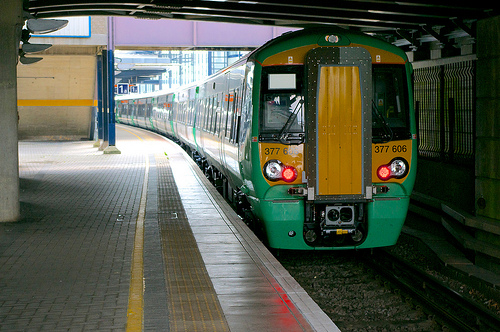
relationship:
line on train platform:
[112, 125, 160, 330] [7, 113, 279, 330]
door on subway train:
[315, 61, 367, 209] [114, 27, 427, 254]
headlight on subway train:
[258, 155, 301, 188] [114, 27, 427, 254]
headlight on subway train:
[374, 147, 414, 188] [114, 27, 427, 254]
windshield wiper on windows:
[278, 94, 302, 147] [261, 63, 308, 144]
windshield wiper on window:
[372, 94, 399, 143] [370, 53, 412, 147]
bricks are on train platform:
[121, 193, 133, 229] [14, 115, 306, 330]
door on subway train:
[315, 64, 367, 197] [114, 27, 417, 254]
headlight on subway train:
[262, 158, 299, 184] [114, 27, 427, 254]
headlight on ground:
[262, 158, 299, 184] [36, 139, 285, 330]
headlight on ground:
[375, 156, 410, 181] [36, 139, 285, 330]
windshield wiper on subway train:
[278, 95, 306, 142] [114, 27, 427, 254]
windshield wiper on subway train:
[372, 98, 399, 142] [114, 27, 427, 254]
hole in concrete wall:
[472, 194, 492, 214] [472, 20, 498, 223]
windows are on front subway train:
[261, 57, 419, 148] [114, 27, 427, 254]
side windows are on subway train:
[110, 86, 251, 144] [114, 27, 427, 254]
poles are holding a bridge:
[90, 51, 120, 159] [13, 13, 308, 143]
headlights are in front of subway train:
[281, 166, 299, 182] [114, 27, 427, 254]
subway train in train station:
[114, 27, 427, 254] [0, 1, 492, 331]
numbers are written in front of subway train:
[260, 139, 410, 159] [114, 27, 427, 254]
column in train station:
[0, 0, 25, 228] [0, 1, 492, 331]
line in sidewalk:
[112, 118, 160, 330] [3, 113, 340, 331]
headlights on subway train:
[263, 161, 407, 180] [114, 27, 417, 254]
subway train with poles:
[114, 27, 417, 254] [94, 46, 116, 147]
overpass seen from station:
[108, 15, 302, 51] [3, 1, 498, 331]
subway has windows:
[115, 28, 417, 254] [115, 63, 250, 143]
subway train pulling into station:
[114, 27, 417, 254] [3, 1, 498, 331]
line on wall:
[16, 97, 96, 108] [14, 16, 98, 142]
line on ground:
[112, 125, 160, 330] [3, 121, 329, 331]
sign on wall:
[27, 15, 90, 40] [14, 16, 98, 142]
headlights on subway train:
[281, 166, 299, 182] [114, 27, 427, 254]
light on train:
[115, 31, 416, 250] [377, 164, 389, 179]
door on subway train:
[315, 64, 367, 197] [114, 27, 427, 254]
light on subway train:
[263, 159, 281, 182] [114, 27, 427, 254]